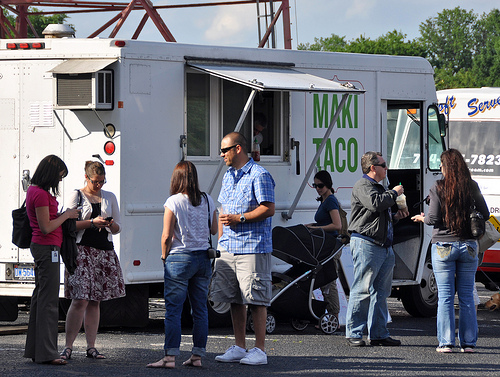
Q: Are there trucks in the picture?
A: Yes, there is a truck.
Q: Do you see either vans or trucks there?
A: Yes, there is a truck.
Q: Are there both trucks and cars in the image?
A: No, there is a truck but no cars.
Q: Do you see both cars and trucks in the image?
A: No, there is a truck but no cars.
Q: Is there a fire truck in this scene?
A: No, there are no fire trucks.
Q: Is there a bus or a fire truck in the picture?
A: No, there are no fire trucks or buses.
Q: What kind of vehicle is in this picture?
A: The vehicle is a truck.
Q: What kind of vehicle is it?
A: The vehicle is a truck.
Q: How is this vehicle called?
A: This is a truck.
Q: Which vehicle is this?
A: This is a truck.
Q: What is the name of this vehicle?
A: This is a truck.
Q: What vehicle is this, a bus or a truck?
A: This is a truck.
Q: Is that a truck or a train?
A: That is a truck.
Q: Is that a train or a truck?
A: That is a truck.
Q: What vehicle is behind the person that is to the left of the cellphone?
A: The vehicle is a truck.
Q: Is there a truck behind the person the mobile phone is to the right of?
A: Yes, there is a truck behind the person.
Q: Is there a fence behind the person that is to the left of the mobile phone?
A: No, there is a truck behind the person.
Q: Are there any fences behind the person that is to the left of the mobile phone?
A: No, there is a truck behind the person.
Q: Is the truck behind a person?
A: Yes, the truck is behind a person.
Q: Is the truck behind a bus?
A: No, the truck is behind a person.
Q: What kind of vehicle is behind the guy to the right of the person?
A: The vehicle is a truck.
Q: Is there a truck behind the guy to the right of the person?
A: Yes, there is a truck behind the guy.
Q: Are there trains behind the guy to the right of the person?
A: No, there is a truck behind the guy.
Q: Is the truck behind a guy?
A: Yes, the truck is behind a guy.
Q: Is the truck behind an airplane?
A: No, the truck is behind a guy.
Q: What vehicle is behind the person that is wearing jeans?
A: The vehicle is a truck.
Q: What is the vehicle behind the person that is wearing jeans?
A: The vehicle is a truck.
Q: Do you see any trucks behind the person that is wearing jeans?
A: Yes, there is a truck behind the person.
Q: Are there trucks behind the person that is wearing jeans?
A: Yes, there is a truck behind the person.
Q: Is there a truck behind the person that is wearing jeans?
A: Yes, there is a truck behind the person.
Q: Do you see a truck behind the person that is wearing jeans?
A: Yes, there is a truck behind the person.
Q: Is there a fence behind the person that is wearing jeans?
A: No, there is a truck behind the person.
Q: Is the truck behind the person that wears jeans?
A: Yes, the truck is behind the person.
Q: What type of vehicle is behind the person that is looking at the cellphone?
A: The vehicle is a truck.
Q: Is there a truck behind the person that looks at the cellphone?
A: Yes, there is a truck behind the person.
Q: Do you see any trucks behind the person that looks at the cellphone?
A: Yes, there is a truck behind the person.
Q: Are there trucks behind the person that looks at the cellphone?
A: Yes, there is a truck behind the person.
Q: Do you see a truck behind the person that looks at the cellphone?
A: Yes, there is a truck behind the person.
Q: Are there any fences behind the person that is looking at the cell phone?
A: No, there is a truck behind the person.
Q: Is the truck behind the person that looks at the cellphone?
A: Yes, the truck is behind the person.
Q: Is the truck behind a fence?
A: No, the truck is behind the person.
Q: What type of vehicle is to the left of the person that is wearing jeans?
A: The vehicle is a truck.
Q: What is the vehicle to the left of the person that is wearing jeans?
A: The vehicle is a truck.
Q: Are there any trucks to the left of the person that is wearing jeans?
A: Yes, there is a truck to the left of the person.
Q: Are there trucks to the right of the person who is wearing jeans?
A: No, the truck is to the left of the person.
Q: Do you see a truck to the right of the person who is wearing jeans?
A: No, the truck is to the left of the person.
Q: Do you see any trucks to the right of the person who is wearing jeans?
A: No, the truck is to the left of the person.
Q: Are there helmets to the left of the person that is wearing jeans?
A: No, there is a truck to the left of the person.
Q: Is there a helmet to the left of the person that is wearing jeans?
A: No, there is a truck to the left of the person.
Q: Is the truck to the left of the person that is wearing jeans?
A: Yes, the truck is to the left of the person.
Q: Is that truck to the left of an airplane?
A: No, the truck is to the left of the person.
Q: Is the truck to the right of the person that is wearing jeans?
A: No, the truck is to the left of the person.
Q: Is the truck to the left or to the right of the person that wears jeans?
A: The truck is to the left of the person.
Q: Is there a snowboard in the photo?
A: No, there are no snowboards.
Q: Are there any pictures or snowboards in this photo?
A: No, there are no snowboards or pictures.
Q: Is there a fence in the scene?
A: No, there are no fences.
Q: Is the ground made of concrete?
A: Yes, the ground is made of concrete.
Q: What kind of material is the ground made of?
A: The ground is made of concrete.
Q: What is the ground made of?
A: The ground is made of concrete.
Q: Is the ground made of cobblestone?
A: No, the ground is made of cement.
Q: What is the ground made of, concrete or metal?
A: The ground is made of concrete.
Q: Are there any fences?
A: No, there are no fences.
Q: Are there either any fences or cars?
A: No, there are no fences or cars.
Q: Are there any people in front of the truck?
A: Yes, there is a person in front of the truck.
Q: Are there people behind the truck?
A: No, the person is in front of the truck.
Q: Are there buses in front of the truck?
A: No, there is a person in front of the truck.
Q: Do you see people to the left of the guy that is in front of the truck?
A: Yes, there is a person to the left of the guy.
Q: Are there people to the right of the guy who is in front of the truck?
A: No, the person is to the left of the guy.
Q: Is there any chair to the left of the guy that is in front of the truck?
A: No, there is a person to the left of the guy.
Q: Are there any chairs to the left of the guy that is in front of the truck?
A: No, there is a person to the left of the guy.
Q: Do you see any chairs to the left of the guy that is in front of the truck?
A: No, there is a person to the left of the guy.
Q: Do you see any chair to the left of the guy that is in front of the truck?
A: No, there is a person to the left of the guy.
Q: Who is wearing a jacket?
A: The guy is wearing a jacket.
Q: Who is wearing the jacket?
A: The guy is wearing a jacket.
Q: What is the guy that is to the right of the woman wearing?
A: The guy is wearing a jacket.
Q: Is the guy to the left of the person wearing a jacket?
A: Yes, the guy is wearing a jacket.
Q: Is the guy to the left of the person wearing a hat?
A: No, the guy is wearing a jacket.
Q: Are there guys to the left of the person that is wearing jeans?
A: Yes, there is a guy to the left of the person.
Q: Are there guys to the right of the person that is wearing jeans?
A: No, the guy is to the left of the person.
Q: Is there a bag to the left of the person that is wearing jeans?
A: No, there is a guy to the left of the person.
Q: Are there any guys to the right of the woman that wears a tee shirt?
A: Yes, there is a guy to the right of the woman.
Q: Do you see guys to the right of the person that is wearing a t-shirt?
A: Yes, there is a guy to the right of the woman.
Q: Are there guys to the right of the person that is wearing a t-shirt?
A: Yes, there is a guy to the right of the woman.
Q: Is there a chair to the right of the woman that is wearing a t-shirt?
A: No, there is a guy to the right of the woman.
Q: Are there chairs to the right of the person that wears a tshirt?
A: No, there is a guy to the right of the woman.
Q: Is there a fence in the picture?
A: No, there are no fences.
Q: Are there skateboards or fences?
A: No, there are no fences or skateboards.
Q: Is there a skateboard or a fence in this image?
A: No, there are no fences or skateboards.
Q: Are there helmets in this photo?
A: No, there are no helmets.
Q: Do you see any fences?
A: No, there are no fences.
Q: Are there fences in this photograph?
A: No, there are no fences.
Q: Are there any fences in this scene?
A: No, there are no fences.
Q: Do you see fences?
A: No, there are no fences.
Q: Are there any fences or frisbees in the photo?
A: No, there are no fences or frisbees.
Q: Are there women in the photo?
A: Yes, there is a woman.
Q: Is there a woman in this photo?
A: Yes, there is a woman.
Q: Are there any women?
A: Yes, there is a woman.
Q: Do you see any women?
A: Yes, there is a woman.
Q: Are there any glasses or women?
A: Yes, there is a woman.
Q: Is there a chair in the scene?
A: No, there are no chairs.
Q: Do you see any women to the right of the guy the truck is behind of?
A: Yes, there is a woman to the right of the guy.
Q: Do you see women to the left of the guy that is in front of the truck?
A: No, the woman is to the right of the guy.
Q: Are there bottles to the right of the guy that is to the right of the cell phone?
A: No, there is a woman to the right of the guy.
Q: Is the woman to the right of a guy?
A: Yes, the woman is to the right of a guy.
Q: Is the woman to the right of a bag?
A: No, the woman is to the right of a guy.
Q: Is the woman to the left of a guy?
A: No, the woman is to the right of a guy.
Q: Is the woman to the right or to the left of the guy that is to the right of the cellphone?
A: The woman is to the right of the guy.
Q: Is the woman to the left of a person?
A: No, the woman is to the right of a person.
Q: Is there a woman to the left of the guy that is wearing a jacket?
A: Yes, there is a woman to the left of the guy.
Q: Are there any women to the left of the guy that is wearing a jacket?
A: Yes, there is a woman to the left of the guy.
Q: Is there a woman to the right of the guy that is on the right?
A: No, the woman is to the left of the guy.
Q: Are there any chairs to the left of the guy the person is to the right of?
A: No, there is a woman to the left of the guy.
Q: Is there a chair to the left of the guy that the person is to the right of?
A: No, there is a woman to the left of the guy.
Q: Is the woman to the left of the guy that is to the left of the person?
A: Yes, the woman is to the left of the guy.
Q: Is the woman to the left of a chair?
A: No, the woman is to the left of the guy.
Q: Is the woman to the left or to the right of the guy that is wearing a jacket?
A: The woman is to the left of the guy.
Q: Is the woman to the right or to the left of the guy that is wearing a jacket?
A: The woman is to the left of the guy.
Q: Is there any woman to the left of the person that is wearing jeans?
A: Yes, there is a woman to the left of the person.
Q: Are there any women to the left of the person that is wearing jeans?
A: Yes, there is a woman to the left of the person.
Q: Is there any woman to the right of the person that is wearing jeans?
A: No, the woman is to the left of the person.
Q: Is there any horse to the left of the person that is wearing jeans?
A: No, there is a woman to the left of the person.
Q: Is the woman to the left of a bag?
A: No, the woman is to the left of a person.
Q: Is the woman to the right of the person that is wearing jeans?
A: No, the woman is to the left of the person.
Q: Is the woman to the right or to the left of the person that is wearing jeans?
A: The woman is to the left of the person.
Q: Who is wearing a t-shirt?
A: The woman is wearing a t-shirt.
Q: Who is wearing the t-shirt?
A: The woman is wearing a t-shirt.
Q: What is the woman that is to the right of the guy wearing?
A: The woman is wearing a tshirt.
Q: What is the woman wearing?
A: The woman is wearing a tshirt.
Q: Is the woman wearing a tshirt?
A: Yes, the woman is wearing a tshirt.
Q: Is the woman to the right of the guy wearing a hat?
A: No, the woman is wearing a tshirt.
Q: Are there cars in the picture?
A: No, there are no cars.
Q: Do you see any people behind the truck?
A: No, the person is in front of the truck.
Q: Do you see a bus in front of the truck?
A: No, there is a person in front of the truck.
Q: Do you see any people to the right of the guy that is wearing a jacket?
A: Yes, there is a person to the right of the guy.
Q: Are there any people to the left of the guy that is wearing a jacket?
A: No, the person is to the right of the guy.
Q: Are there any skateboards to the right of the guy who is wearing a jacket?
A: No, there is a person to the right of the guy.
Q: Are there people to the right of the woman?
A: Yes, there is a person to the right of the woman.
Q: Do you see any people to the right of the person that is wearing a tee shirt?
A: Yes, there is a person to the right of the woman.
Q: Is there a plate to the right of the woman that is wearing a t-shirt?
A: No, there is a person to the right of the woman.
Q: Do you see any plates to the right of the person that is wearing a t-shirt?
A: No, there is a person to the right of the woman.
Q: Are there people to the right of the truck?
A: Yes, there is a person to the right of the truck.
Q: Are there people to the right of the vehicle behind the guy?
A: Yes, there is a person to the right of the truck.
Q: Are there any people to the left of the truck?
A: No, the person is to the right of the truck.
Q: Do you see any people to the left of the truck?
A: No, the person is to the right of the truck.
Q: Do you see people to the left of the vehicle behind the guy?
A: No, the person is to the right of the truck.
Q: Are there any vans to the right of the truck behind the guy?
A: No, there is a person to the right of the truck.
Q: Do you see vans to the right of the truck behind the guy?
A: No, there is a person to the right of the truck.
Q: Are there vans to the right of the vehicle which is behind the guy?
A: No, there is a person to the right of the truck.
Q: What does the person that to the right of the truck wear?
A: The person wears jeans.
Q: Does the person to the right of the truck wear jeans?
A: Yes, the person wears jeans.